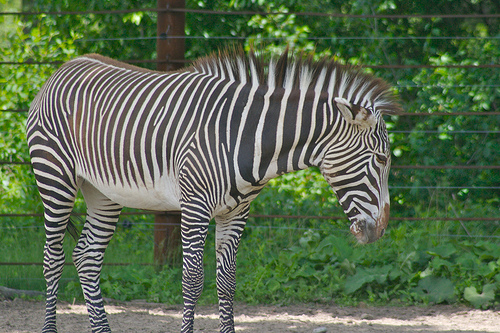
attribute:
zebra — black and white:
[24, 42, 423, 295]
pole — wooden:
[153, 2, 185, 269]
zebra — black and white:
[35, 54, 387, 320]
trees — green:
[3, 2, 495, 312]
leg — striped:
[30, 154, 83, 331]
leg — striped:
[72, 174, 125, 331]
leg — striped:
[172, 191, 214, 331]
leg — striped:
[210, 197, 251, 332]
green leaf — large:
[418, 249, 498, 315]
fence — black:
[0, 13, 499, 291]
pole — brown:
[154, 14, 183, 266]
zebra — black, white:
[78, 44, 452, 214]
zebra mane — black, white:
[179, 45, 409, 122]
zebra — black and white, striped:
[25, 42, 391, 332]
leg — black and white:
[180, 201, 210, 332]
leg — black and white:
[213, 205, 248, 332]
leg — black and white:
[72, 188, 122, 332]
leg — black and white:
[25, 130, 77, 332]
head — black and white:
[323, 91, 398, 251]